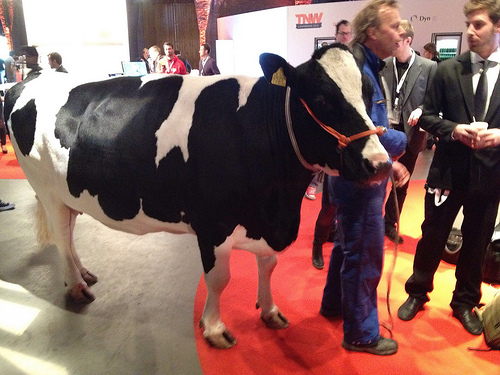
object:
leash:
[282, 85, 399, 340]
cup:
[469, 121, 488, 131]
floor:
[24, 86, 484, 356]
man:
[155, 41, 186, 75]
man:
[380, 17, 439, 245]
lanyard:
[390, 48, 415, 108]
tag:
[389, 108, 401, 125]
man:
[317, 0, 411, 355]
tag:
[270, 67, 287, 87]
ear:
[257, 52, 295, 89]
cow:
[0, 41, 393, 351]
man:
[395, 0, 499, 336]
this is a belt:
[284, 85, 326, 183]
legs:
[188, 220, 278, 310]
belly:
[67, 192, 197, 236]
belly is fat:
[88, 177, 156, 224]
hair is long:
[347, 0, 396, 48]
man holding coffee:
[453, 120, 499, 152]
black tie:
[472, 59, 492, 122]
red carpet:
[192, 257, 459, 373]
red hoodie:
[158, 54, 187, 75]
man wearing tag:
[157, 55, 186, 74]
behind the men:
[125, 7, 353, 73]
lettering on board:
[284, 4, 345, 36]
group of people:
[312, 3, 500, 373]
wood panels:
[125, 0, 199, 69]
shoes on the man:
[397, 295, 430, 321]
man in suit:
[402, 48, 500, 311]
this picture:
[0, 0, 500, 375]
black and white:
[5, 42, 394, 280]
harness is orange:
[196, 187, 466, 373]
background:
[0, 0, 463, 90]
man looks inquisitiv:
[395, 0, 500, 336]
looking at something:
[451, 1, 499, 61]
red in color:
[158, 55, 187, 75]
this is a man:
[197, 43, 221, 76]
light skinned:
[345, 1, 415, 64]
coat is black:
[416, 50, 500, 192]